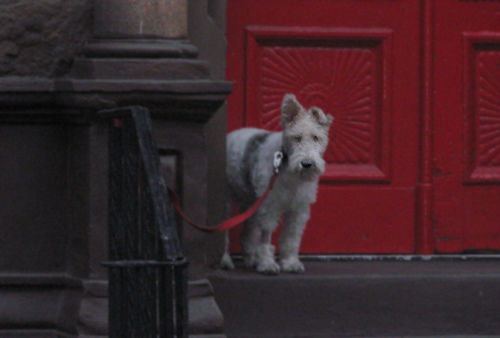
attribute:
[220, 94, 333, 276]
dog — brown, white, medium sized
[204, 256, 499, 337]
stoop — concrete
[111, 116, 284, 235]
leash — red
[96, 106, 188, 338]
handrail — black, iron, wrought iron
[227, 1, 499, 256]
doors — red, ornate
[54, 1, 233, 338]
post — concrete, marble, ornate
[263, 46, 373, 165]
design — carved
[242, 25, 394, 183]
frame — square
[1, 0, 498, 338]
building — concrete, grey, stone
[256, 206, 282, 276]
leg — shaved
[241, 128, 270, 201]
strip — black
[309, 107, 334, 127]
ear — folded over, down, folded down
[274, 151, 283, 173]
clasp — silver, metal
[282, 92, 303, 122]
one ear — up